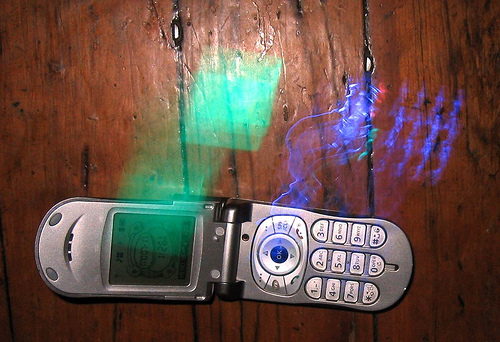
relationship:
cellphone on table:
[34, 193, 416, 312] [3, 2, 483, 336]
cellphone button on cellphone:
[269, 245, 291, 264] [34, 193, 416, 312]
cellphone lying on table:
[34, 193, 416, 312] [0, 0, 500, 342]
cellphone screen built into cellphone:
[92, 191, 207, 312] [34, 193, 416, 312]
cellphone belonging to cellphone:
[34, 193, 416, 312] [34, 193, 416, 312]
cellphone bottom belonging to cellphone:
[232, 189, 422, 326] [34, 193, 416, 312]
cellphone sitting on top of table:
[34, 193, 416, 312] [0, 0, 500, 342]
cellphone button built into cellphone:
[269, 245, 291, 264] [34, 193, 416, 312]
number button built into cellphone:
[304, 274, 322, 301] [34, 193, 416, 312]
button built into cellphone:
[310, 248, 328, 270] [34, 193, 416, 312]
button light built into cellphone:
[310, 219, 328, 243] [34, 193, 416, 312]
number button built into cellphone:
[332, 215, 349, 247] [34, 193, 416, 312]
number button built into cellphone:
[325, 279, 341, 301] [34, 193, 416, 312]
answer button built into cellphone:
[281, 267, 304, 296] [34, 193, 416, 312]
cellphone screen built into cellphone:
[107, 212, 196, 286] [34, 193, 416, 312]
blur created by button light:
[276, 89, 467, 201] [270, 212, 296, 234]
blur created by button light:
[276, 89, 467, 201] [307, 217, 330, 244]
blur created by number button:
[276, 89, 467, 201] [325, 279, 341, 301]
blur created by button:
[276, 89, 467, 201] [349, 252, 366, 275]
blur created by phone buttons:
[276, 89, 467, 201] [265, 276, 287, 300]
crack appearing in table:
[345, 4, 387, 213] [3, 2, 483, 336]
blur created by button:
[256, 70, 467, 261] [271, 213, 295, 233]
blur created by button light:
[256, 70, 467, 261] [310, 219, 328, 243]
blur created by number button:
[256, 70, 467, 261] [332, 215, 349, 247]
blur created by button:
[256, 70, 467, 261] [343, 281, 358, 304]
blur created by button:
[256, 70, 467, 261] [366, 251, 385, 277]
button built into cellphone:
[341, 277, 361, 304] [34, 193, 416, 312]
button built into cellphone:
[346, 249, 366, 275] [34, 193, 416, 312]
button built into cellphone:
[350, 220, 368, 249] [34, 193, 416, 312]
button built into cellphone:
[369, 223, 388, 249] [34, 193, 416, 312]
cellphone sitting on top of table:
[34, 193, 416, 312] [3, 2, 483, 336]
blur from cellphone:
[256, 70, 467, 261] [34, 193, 416, 312]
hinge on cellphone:
[221, 194, 251, 327] [34, 193, 416, 312]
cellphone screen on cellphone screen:
[107, 212, 196, 286] [107, 212, 196, 286]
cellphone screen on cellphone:
[107, 212, 196, 286] [34, 193, 416, 312]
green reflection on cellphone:
[132, 28, 283, 195] [34, 193, 416, 312]